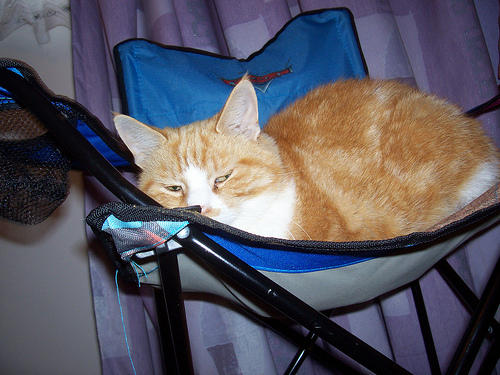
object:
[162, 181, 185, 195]
cat eyes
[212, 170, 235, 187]
cat eyes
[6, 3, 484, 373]
photo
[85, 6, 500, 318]
animal magazine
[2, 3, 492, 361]
dayton city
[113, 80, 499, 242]
cat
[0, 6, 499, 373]
chair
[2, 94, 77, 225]
net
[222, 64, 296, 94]
logo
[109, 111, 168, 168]
cat's ear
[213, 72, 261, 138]
cat's ear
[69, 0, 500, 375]
curtain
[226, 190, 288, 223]
whisker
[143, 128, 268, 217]
cat's face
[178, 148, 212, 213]
spot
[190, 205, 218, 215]
cat's nose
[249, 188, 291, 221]
spot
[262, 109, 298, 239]
cat's neck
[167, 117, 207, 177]
stripes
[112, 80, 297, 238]
cat's head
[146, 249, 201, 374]
seat leg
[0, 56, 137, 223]
mesh cupholder